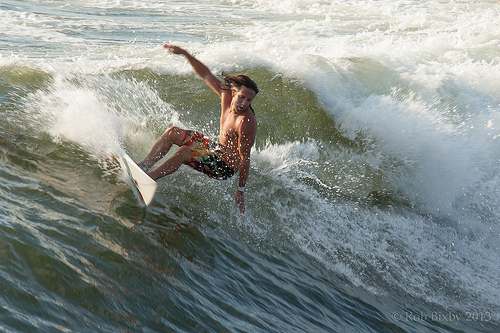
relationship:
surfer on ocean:
[134, 41, 259, 213] [1, 1, 498, 331]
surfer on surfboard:
[134, 41, 259, 213] [121, 148, 158, 204]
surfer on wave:
[134, 41, 259, 213] [0, 41, 497, 331]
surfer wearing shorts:
[134, 41, 259, 213] [178, 128, 237, 182]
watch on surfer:
[236, 183, 249, 194] [134, 41, 259, 213]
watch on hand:
[236, 183, 249, 194] [233, 189, 247, 216]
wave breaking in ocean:
[0, 41, 497, 331] [1, 1, 498, 331]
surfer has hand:
[134, 41, 259, 213] [233, 189, 247, 216]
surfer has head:
[134, 41, 259, 213] [233, 80, 257, 114]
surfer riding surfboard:
[134, 41, 259, 213] [121, 148, 158, 204]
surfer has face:
[134, 41, 259, 213] [234, 89, 253, 112]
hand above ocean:
[233, 189, 247, 216] [1, 1, 498, 331]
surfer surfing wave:
[134, 41, 259, 213] [0, 41, 497, 331]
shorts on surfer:
[178, 128, 237, 182] [134, 41, 259, 213]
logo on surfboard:
[133, 178, 144, 204] [121, 148, 158, 204]